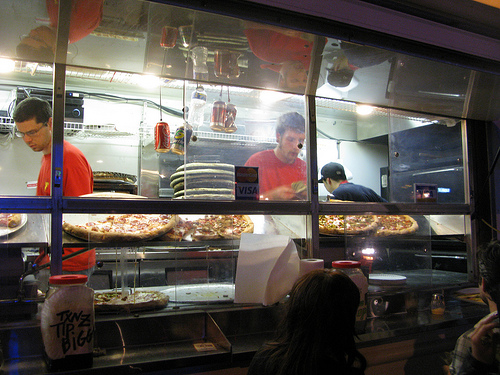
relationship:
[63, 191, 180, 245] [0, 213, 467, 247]
whole pizza on shelf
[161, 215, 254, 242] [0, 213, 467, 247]
whole pizza on shelf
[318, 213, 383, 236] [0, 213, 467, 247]
whole pizza on shelf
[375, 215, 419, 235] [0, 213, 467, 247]
whole pizza on shelf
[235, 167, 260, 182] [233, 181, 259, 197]
credit card on credit card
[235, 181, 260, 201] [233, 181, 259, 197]
credit card on credit card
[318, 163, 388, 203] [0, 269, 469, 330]
chef behind counter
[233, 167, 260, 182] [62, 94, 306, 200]
credit card on window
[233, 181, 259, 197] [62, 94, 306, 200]
credit card on window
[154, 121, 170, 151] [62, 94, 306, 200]
soda in window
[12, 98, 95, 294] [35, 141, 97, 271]
man wearing a shirt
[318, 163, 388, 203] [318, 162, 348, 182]
man wearing a baseball hat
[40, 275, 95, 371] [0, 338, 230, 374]
tip jar on ledge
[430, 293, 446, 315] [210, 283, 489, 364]
parmesan cheese on ledge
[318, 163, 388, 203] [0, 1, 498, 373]
chef working in food truck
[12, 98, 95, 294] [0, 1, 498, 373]
man working in food truck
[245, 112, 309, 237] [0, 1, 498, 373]
worker working in food truck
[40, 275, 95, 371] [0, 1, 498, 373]
tip jar on food truck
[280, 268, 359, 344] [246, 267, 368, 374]
head of person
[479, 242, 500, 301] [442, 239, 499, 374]
head of person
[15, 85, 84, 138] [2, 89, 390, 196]
radio against wall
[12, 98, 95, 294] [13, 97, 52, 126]
man has hair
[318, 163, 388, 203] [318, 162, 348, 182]
chef wearing a baseball hat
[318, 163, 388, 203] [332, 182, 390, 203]
chef wearing a shirt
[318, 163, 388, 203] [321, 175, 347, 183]
chef has hair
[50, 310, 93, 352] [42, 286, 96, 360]
writing on plate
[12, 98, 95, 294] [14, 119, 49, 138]
man wearing glasses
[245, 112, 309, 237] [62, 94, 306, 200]
worker near window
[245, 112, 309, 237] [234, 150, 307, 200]
worker wearing a shirt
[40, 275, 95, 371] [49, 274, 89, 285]
tip jar has a lid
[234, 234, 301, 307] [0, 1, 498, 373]
paper on food truck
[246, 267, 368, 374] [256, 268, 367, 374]
person has hair